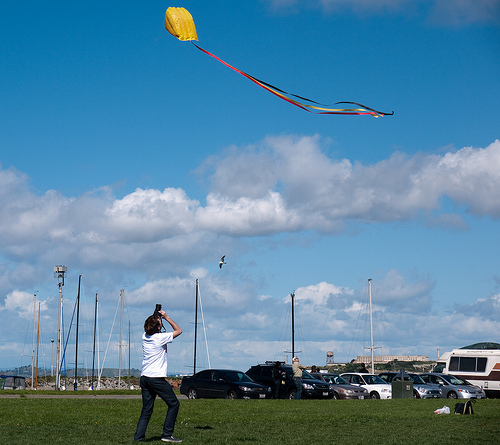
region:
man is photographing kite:
[124, 304, 192, 444]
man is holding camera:
[138, 302, 183, 342]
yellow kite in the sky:
[155, 2, 397, 132]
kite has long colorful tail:
[190, 40, 395, 129]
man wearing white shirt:
[130, 330, 175, 380]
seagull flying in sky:
[211, 255, 227, 270]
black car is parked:
[179, 370, 269, 405]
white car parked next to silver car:
[319, 366, 439, 406]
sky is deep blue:
[1, 2, 497, 365]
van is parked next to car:
[417, 349, 498, 394]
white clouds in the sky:
[153, 106, 328, 258]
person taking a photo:
[127, 283, 204, 384]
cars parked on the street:
[310, 351, 400, 415]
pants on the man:
[118, 375, 190, 421]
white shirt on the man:
[136, 331, 173, 366]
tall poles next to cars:
[19, 267, 116, 379]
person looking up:
[286, 348, 317, 400]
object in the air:
[136, 11, 268, 96]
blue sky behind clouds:
[311, 228, 370, 284]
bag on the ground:
[439, 395, 480, 425]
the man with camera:
[118, 302, 199, 442]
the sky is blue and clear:
[46, 17, 144, 129]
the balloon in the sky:
[159, 6, 416, 140]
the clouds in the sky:
[78, 215, 175, 285]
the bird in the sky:
[208, 250, 234, 275]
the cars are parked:
[182, 354, 499, 400]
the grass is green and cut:
[231, 407, 404, 443]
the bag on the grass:
[453, 392, 480, 416]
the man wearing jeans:
[133, 303, 184, 443]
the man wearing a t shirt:
[131, 305, 201, 437]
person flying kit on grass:
[24, 7, 414, 441]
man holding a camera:
[54, 201, 304, 443]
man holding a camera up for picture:
[90, 228, 227, 433]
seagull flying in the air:
[181, 190, 292, 284]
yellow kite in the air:
[114, 2, 381, 197]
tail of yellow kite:
[150, 50, 470, 195]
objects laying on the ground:
[424, 398, 479, 425]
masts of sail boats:
[0, 260, 161, 407]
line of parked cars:
[175, 328, 473, 420]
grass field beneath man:
[25, 395, 387, 439]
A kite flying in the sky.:
[155, 5, 395, 135]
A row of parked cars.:
[175, 330, 495, 410]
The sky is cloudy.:
[20, 140, 410, 335]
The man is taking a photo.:
[115, 290, 195, 440]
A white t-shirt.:
[130, 330, 170, 380]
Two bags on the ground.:
[425, 390, 475, 425]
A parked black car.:
[175, 360, 275, 410]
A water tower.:
[320, 340, 337, 363]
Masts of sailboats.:
[20, 285, 135, 385]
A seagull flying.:
[205, 246, 235, 271]